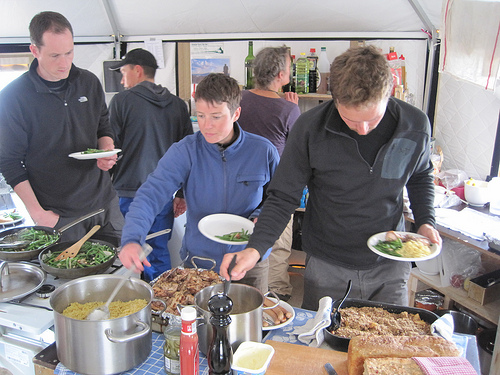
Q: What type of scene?
A: Indoor.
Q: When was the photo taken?
A: Daytime.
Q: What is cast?
A: Shadow.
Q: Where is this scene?
A: Kitchen.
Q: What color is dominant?
A: White.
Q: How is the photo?
A: Clear.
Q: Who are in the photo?
A: People.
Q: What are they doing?
A: Serving food.